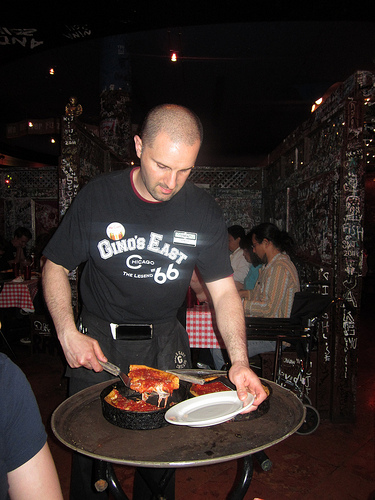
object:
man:
[40, 100, 265, 497]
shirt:
[38, 166, 235, 326]